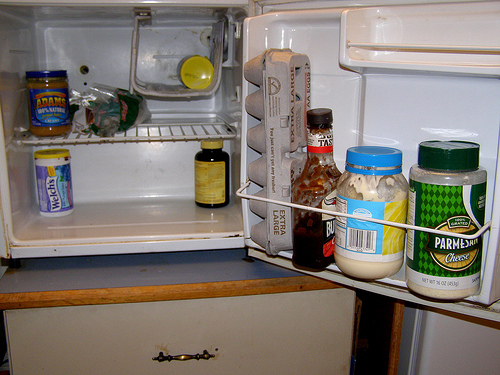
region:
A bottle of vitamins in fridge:
[192, 139, 229, 206]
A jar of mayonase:
[335, 144, 404, 280]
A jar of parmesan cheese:
[405, 137, 489, 302]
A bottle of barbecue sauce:
[287, 105, 342, 270]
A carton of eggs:
[243, 47, 312, 257]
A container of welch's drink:
[30, 147, 76, 216]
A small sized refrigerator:
[0, 0, 499, 324]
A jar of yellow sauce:
[21, 66, 70, 136]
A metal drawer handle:
[150, 350, 215, 364]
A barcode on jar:
[344, 227, 377, 253]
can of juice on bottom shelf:
[31, 149, 80, 216]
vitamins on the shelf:
[190, 134, 232, 211]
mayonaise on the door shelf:
[333, 145, 404, 281]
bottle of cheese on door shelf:
[406, 136, 479, 295]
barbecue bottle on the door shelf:
[292, 106, 331, 267]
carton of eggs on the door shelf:
[242, 47, 306, 254]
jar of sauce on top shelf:
[26, 65, 73, 135]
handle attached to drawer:
[155, 347, 213, 363]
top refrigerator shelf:
[16, 134, 233, 146]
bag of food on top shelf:
[76, 85, 155, 137]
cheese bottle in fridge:
[420, 151, 477, 286]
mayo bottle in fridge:
[337, 155, 392, 302]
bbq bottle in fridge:
[291, 142, 321, 242]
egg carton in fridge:
[260, 110, 295, 225]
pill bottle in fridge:
[197, 150, 247, 221]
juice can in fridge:
[25, 160, 100, 235]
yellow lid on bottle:
[180, 65, 215, 81]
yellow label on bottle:
[190, 155, 245, 240]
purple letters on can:
[32, 171, 72, 216]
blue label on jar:
[355, 195, 400, 261]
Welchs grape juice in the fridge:
[32, 148, 77, 222]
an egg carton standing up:
[237, 35, 306, 260]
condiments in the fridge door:
[288, 109, 411, 284]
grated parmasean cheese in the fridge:
[402, 138, 490, 308]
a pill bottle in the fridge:
[191, 143, 233, 213]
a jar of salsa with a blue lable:
[23, 58, 74, 140]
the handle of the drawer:
[137, 333, 227, 374]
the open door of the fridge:
[248, 6, 499, 329]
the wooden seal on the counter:
[4, 276, 341, 308]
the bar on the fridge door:
[237, 175, 499, 240]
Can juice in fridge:
[24, 150, 78, 227]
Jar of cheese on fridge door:
[399, 121, 494, 309]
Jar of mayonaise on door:
[328, 139, 412, 286]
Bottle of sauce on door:
[287, 108, 348, 272]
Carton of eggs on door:
[231, 43, 310, 262]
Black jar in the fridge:
[189, 136, 236, 215]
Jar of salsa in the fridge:
[13, 48, 80, 145]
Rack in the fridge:
[11, 115, 241, 157]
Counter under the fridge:
[0, 269, 367, 374]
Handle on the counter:
[134, 341, 221, 373]